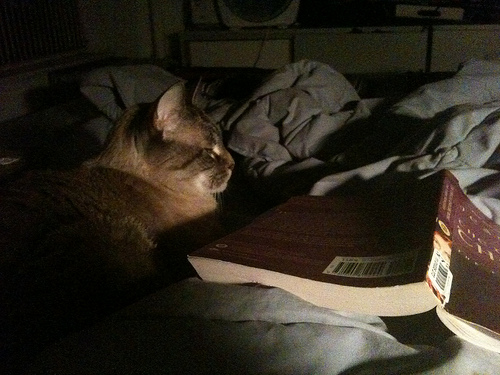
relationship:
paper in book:
[188, 258, 433, 318] [179, 162, 498, 349]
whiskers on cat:
[198, 178, 226, 205] [11, 64, 251, 365]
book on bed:
[179, 162, 498, 349] [5, 20, 491, 373]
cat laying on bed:
[6, 78, 237, 351] [5, 20, 491, 373]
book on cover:
[179, 162, 498, 349] [188, 301, 321, 362]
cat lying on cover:
[6, 78, 237, 351] [85, 289, 331, 365]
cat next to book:
[1, 69, 236, 365] [179, 162, 498, 349]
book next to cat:
[168, 155, 498, 363] [6, 78, 237, 351]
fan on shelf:
[215, 0, 299, 33] [162, 21, 436, 65]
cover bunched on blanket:
[230, 67, 485, 167] [233, 31, 494, 171]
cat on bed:
[50, 135, 219, 237] [207, 314, 315, 370]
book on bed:
[290, 169, 496, 328] [202, 321, 303, 356]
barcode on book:
[321, 246, 456, 306] [288, 177, 459, 256]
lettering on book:
[277, 212, 331, 245] [297, 167, 497, 316]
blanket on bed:
[303, 88, 394, 143] [134, 294, 295, 372]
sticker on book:
[421, 211, 462, 245] [368, 164, 483, 298]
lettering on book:
[396, 190, 492, 255] [314, 178, 497, 319]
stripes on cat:
[62, 166, 162, 230] [76, 121, 222, 222]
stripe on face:
[170, 138, 228, 189] [167, 98, 255, 205]